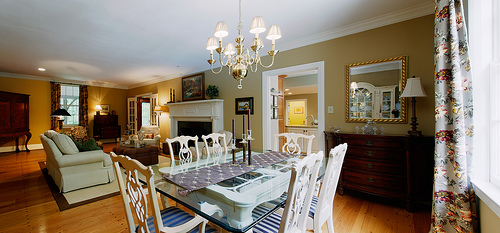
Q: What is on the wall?
A: A mirror.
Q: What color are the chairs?
A: White.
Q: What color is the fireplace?
A: White.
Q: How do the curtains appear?
A: Open.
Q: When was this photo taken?
A: In the daytime.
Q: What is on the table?
A: Candle holders.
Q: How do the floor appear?
A: Shiny.